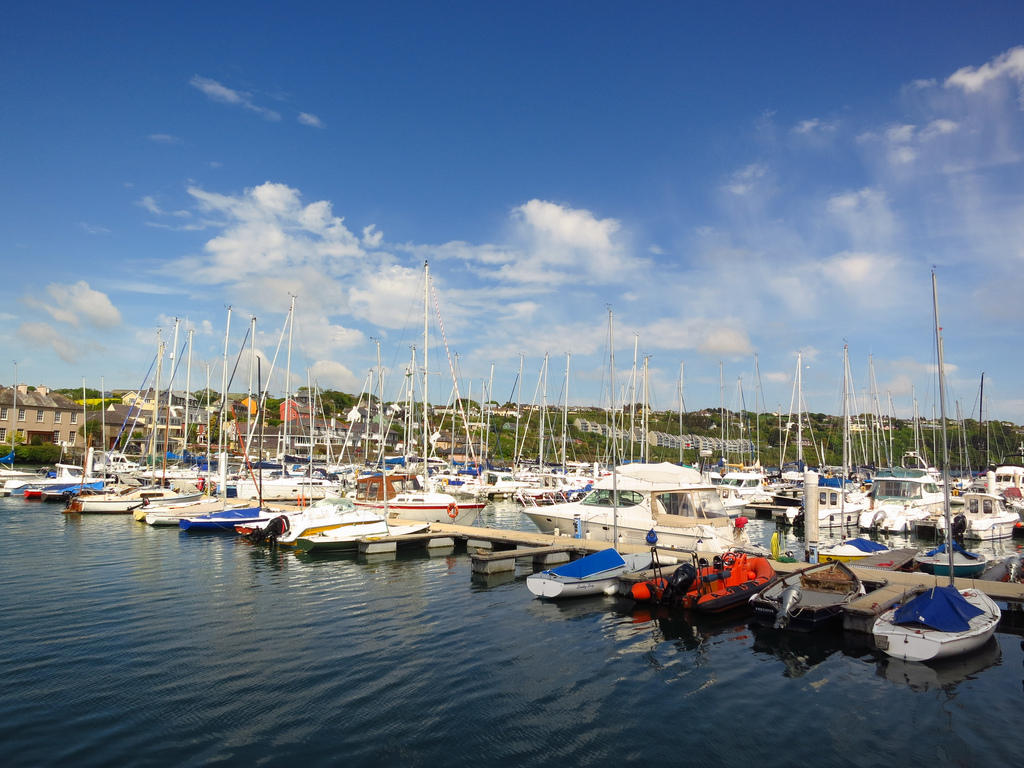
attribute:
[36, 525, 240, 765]
water — large water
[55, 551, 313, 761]
water — large body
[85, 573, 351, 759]
water — large body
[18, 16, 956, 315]
fluffy cloud — white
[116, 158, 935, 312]
fluffy cloud — white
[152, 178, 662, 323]
fluffy cloud — white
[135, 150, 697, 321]
fluffy cloud — white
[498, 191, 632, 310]
fluffy cloud — white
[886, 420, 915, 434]
leaves — green 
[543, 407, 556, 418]
leaves — green 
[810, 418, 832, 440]
leaves — green 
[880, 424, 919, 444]
leaves — green  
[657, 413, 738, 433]
leaves — green 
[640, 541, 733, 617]
boat — red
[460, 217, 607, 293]
cloud — white 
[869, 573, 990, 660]
boat — white , blue 